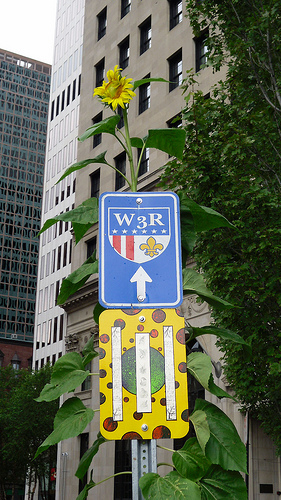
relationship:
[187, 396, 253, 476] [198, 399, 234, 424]
leaf has edge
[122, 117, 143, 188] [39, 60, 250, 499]
stalk of plant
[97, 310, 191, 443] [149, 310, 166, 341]
sign has circles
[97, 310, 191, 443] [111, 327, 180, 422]
sign has stripes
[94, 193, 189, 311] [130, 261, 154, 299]
sign has arrow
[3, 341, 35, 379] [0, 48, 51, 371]
bricks on building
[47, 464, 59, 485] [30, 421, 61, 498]
sign in window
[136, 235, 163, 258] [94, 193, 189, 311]
fur de les on sign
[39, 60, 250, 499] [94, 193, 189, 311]
plant behind sign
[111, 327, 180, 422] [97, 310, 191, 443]
stripes on sign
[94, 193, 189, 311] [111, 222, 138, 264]
sign has flag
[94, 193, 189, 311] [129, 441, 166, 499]
sign on pole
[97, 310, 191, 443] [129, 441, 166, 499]
sign on pole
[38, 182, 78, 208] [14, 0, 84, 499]
window on building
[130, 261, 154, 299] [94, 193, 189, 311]
arrow on sign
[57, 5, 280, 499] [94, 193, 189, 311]
building behind sign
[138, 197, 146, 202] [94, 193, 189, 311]
bolt on sign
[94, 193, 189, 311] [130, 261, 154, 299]
sign has an arrow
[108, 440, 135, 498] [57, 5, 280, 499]
door to building